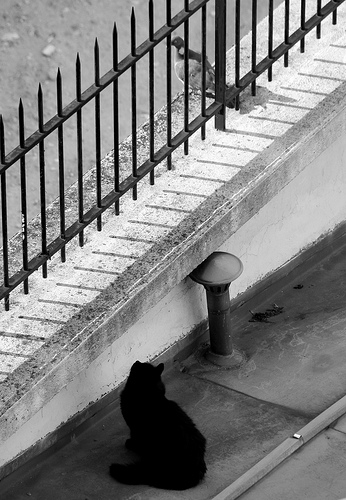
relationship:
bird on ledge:
[173, 34, 241, 106] [3, 0, 344, 406]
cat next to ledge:
[108, 360, 208, 492] [37, 321, 102, 374]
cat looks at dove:
[108, 360, 208, 492] [168, 37, 216, 92]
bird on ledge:
[171, 36, 236, 109] [89, 95, 312, 194]